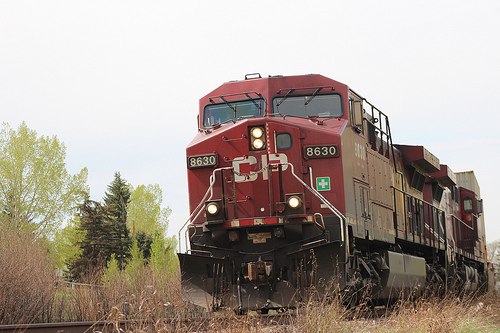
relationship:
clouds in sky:
[0, 1, 499, 281] [21, 1, 498, 68]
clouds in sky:
[393, 77, 441, 134] [440, 20, 498, 104]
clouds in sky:
[409, 34, 479, 116] [0, 2, 498, 242]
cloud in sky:
[299, 6, 435, 71] [0, 2, 498, 242]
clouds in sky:
[96, 39, 155, 163] [0, 2, 498, 242]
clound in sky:
[75, 79, 151, 152] [74, 59, 121, 110]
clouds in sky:
[62, 24, 153, 107] [0, 2, 498, 242]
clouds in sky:
[79, 67, 137, 119] [9, 0, 495, 73]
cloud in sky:
[48, 43, 88, 101] [22, 59, 144, 129]